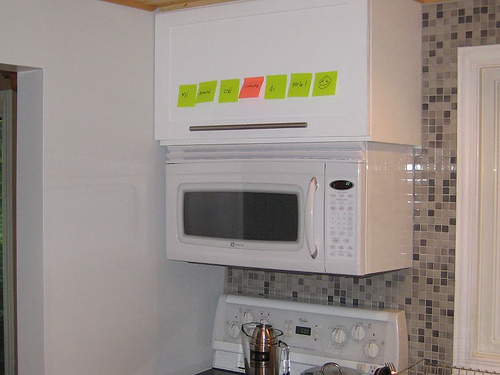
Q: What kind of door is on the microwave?
A: A glass door.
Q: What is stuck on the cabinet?
A: There are seven post its stuck on the cabinet.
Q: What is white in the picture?
A: The top of the stove is white.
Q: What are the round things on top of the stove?
A: They are control knobs.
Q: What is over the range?
A: A white microwave.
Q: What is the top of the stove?
A: It is part of the white oven.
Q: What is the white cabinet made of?
A: It is made of wood.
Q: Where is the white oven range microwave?
A: It is mounted above the stove.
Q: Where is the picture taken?
A: A kitchen.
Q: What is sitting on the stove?
A: Coffee pot.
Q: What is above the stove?
A: Microwave.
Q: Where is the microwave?
A: Above the stove.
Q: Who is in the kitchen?
A: There's nobody.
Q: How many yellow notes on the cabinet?
A: Six notes.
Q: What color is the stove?
A: Pure white.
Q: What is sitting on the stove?
A: A pot.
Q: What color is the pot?
A: Silver steel.